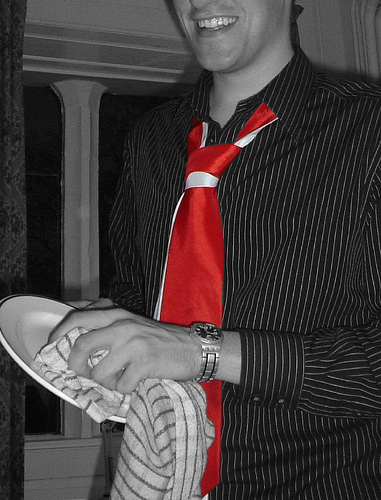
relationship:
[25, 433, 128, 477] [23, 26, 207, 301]
sill on window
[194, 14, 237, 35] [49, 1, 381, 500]
mouth of man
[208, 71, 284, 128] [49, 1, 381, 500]
neck of man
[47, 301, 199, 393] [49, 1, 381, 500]
hand of man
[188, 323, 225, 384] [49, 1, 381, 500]
watch on man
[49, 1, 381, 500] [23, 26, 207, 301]
man in front of window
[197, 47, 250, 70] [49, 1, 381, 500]
chin on man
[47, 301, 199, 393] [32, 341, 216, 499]
hand holding rag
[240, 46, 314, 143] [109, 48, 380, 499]
collar on shirt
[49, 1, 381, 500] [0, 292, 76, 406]
man wiping plate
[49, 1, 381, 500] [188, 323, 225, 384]
man wearing a watch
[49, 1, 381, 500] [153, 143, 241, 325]
man wearing a tie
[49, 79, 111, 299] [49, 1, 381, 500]
post behind man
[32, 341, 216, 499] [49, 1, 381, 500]
rag in hands of man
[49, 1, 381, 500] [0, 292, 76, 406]
man holding onto plate